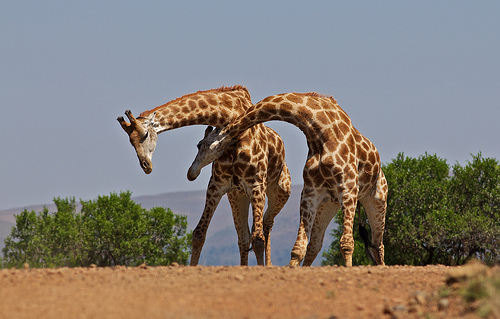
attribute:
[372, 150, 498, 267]
tree — green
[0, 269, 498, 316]
dirt — brown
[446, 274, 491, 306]
grass — green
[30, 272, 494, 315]
dirt — brown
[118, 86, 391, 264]
two giraffe — in a field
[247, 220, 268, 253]
knee — knobby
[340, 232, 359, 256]
knee — knobby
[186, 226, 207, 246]
knee — knobby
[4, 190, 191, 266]
tree tops — green